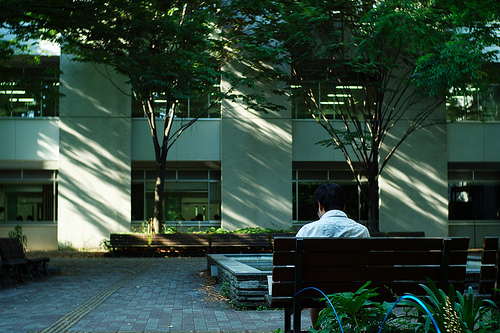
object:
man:
[293, 183, 370, 238]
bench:
[479, 238, 499, 309]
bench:
[264, 236, 472, 316]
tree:
[51, 3, 275, 234]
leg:
[417, 307, 427, 333]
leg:
[293, 308, 302, 332]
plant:
[297, 282, 384, 332]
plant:
[99, 227, 297, 253]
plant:
[394, 278, 496, 331]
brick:
[157, 296, 166, 302]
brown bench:
[206, 254, 495, 308]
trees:
[233, 5, 500, 236]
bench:
[1, 238, 50, 278]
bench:
[109, 233, 297, 257]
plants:
[407, 277, 499, 332]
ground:
[91, 258, 185, 284]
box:
[211, 266, 218, 276]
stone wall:
[207, 255, 270, 312]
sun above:
[37, 116, 165, 228]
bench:
[368, 232, 424, 239]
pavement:
[44, 270, 64, 286]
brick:
[166, 300, 174, 303]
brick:
[214, 310, 227, 321]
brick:
[245, 310, 261, 319]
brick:
[172, 309, 183, 314]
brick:
[138, 311, 150, 318]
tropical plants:
[307, 277, 498, 331]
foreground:
[23, 79, 500, 333]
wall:
[12, 16, 494, 241]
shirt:
[295, 209, 369, 237]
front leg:
[284, 306, 293, 333]